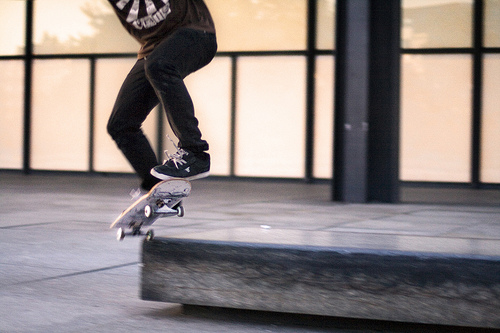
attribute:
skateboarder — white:
[109, 0, 238, 253]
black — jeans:
[111, 30, 213, 165]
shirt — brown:
[96, 0, 214, 48]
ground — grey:
[0, 172, 112, 331]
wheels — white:
[116, 200, 185, 249]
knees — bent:
[90, 49, 174, 148]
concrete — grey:
[152, 202, 486, 294]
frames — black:
[403, 10, 495, 92]